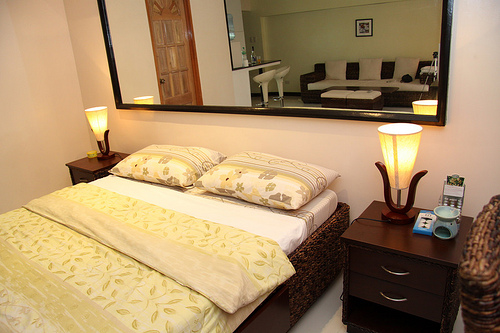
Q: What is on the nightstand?
A: Glowing lamp.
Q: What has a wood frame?
A: The mirror.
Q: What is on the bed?
A: Two pillows.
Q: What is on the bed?
A: A bedspread.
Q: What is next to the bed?
A: A wooden nightstand.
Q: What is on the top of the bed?
A: A pillow.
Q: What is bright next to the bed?
A: A lamp.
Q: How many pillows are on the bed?
A: Two.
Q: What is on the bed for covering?
A: A blanket.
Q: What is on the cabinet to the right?
A: A bedside lamp.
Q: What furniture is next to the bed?
A: Brown wood cabinet with drawers.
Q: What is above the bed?
A: A wide mirror.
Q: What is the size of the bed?
A: A full or queen size bed.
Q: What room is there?
A: Bedroom.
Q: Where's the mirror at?
A: Wall.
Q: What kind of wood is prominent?
A: Cherry wood.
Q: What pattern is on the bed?
A: Floral.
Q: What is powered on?
A: Lamps.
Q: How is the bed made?
A: Neatly.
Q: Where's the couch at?
A: Background.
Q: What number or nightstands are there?
A: 2.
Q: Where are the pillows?
A: Bed.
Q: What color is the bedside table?
A: Brown.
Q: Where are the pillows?
A: On the bed.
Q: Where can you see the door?
A: In the mirror.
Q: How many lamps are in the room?
A: Two.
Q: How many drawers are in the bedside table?
A: Two.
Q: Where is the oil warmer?
A: On the bedside table.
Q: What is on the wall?
A: A picture.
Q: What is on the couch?
A: Pillows.